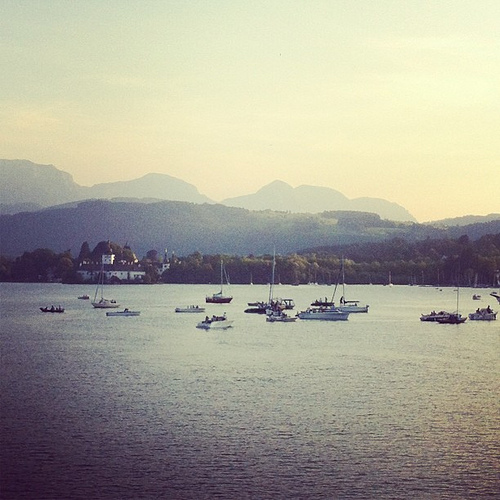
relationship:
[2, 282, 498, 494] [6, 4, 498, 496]
ocean in scene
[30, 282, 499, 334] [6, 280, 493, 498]
boats on water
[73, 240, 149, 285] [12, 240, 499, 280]
building on background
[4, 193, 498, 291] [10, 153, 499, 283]
hills on background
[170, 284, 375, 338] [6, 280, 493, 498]
boats on water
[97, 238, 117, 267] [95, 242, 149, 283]
steeple on house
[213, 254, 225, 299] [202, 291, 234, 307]
pole on boat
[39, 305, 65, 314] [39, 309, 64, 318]
canoe on canoe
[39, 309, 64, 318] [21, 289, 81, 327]
canoe on water